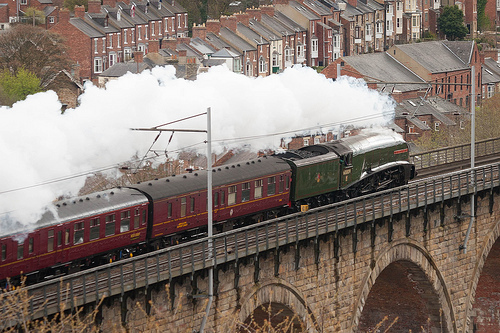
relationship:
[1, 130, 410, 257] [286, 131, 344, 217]
train has a car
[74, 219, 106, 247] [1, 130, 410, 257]
windows are on a train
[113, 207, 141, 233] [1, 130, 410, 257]
windows are on a train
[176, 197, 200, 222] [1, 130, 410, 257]
windows are on a train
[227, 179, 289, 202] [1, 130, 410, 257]
windows are on a train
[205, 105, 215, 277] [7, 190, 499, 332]
pole are on top of a bridge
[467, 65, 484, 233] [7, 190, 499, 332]
pole are on top of a bridge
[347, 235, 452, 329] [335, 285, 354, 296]
arch made of bricks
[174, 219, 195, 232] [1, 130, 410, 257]
words are on side of a train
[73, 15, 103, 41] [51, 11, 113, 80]
roof on top of building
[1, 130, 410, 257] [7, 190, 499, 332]
train on top of bridge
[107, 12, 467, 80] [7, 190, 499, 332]
houses behind bridge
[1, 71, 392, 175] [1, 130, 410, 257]
smoke emitted from train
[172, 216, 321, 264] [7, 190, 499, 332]
train tracks are on top of bridge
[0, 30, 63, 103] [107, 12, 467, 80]
trees in front of houses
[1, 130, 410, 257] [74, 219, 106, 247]
train has windows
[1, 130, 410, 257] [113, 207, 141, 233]
train has windows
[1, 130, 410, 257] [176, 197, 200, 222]
train has windows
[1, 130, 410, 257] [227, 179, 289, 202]
train has windows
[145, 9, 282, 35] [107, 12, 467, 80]
chimneys on top of houses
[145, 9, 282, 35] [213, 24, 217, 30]
chimneys are made of bricks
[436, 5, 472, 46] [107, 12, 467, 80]
tree in front of houses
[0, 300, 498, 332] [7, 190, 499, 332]
plants in front of bridge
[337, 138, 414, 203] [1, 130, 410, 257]
engine at front of a train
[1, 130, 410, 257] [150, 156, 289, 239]
train has a car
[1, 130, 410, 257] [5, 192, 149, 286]
train has a car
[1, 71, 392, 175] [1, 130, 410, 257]
smoke rises from top of a train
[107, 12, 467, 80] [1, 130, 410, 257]
houses are behind train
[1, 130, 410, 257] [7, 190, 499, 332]
train travels on top of a bridge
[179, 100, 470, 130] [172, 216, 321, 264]
cables hang above train tracks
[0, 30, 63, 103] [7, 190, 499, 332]
trees are behind bridge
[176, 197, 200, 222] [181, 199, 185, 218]
windows has shades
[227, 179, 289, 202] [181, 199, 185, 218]
windows has shades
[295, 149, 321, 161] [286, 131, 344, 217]
coal stacked inside car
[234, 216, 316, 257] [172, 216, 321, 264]
railings line side of train tracks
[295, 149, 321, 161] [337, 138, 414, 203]
coal behind engine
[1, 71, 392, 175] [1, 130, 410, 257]
smoke above train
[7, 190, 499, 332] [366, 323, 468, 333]
bridge over river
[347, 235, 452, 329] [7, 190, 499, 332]
arch underneath bridge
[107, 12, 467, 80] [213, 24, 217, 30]
houses are made of bricks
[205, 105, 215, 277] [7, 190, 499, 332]
pole on top of bridge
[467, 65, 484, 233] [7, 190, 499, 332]
pole on top of bridge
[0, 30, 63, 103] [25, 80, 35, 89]
trees have leaves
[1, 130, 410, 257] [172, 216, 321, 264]
train on top of train tracks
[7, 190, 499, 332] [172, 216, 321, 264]
bridge underneath train tracks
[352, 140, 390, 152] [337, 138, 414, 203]
snow covers top of engine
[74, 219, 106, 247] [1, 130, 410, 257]
windows are on train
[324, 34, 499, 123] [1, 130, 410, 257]
buildings to left front of train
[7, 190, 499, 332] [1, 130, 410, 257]
bridge below train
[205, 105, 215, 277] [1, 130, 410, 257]
pole in front of train